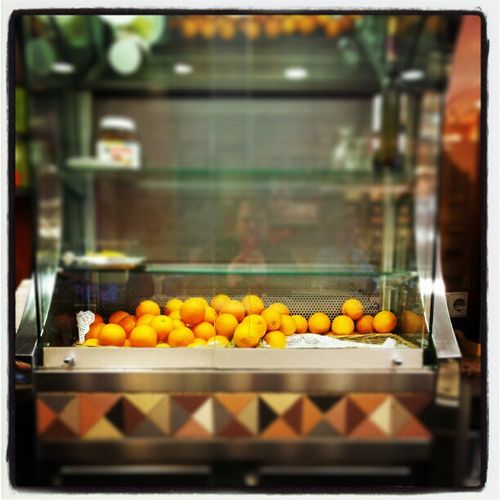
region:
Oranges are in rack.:
[86, 292, 377, 358]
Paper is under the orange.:
[284, 323, 404, 353]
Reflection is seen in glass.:
[78, 120, 361, 290]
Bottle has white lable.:
[62, 108, 173, 192]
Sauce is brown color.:
[91, 115, 141, 179]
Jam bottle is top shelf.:
[83, 109, 147, 180]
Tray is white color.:
[61, 241, 148, 281]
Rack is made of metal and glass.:
[18, 113, 470, 385]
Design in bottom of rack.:
[28, 393, 443, 458]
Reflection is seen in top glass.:
[100, 15, 378, 90]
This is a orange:
[330, 308, 356, 339]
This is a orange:
[342, 294, 364, 319]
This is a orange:
[373, 305, 399, 337]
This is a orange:
[354, 313, 376, 333]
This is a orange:
[398, 305, 425, 337]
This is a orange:
[303, 303, 338, 336]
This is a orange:
[291, 309, 307, 334]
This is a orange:
[277, 311, 297, 334]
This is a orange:
[263, 328, 285, 349]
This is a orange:
[231, 323, 259, 351]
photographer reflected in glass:
[191, 189, 302, 294]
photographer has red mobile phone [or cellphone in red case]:
[237, 227, 263, 264]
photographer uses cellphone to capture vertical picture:
[233, 222, 268, 262]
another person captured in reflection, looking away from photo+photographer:
[296, 202, 379, 297]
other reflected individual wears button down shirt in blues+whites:
[298, 242, 385, 294]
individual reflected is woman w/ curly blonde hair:
[318, 200, 362, 265]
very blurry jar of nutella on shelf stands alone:
[90, 112, 147, 167]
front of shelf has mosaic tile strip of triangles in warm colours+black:
[32, 387, 433, 443]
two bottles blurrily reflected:
[315, 119, 372, 200]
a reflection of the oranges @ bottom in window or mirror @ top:
[157, 12, 362, 55]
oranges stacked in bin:
[94, 288, 289, 364]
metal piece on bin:
[51, 356, 76, 368]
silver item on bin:
[363, 352, 431, 396]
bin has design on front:
[225, 395, 325, 439]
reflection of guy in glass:
[218, 193, 280, 284]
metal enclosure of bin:
[425, 300, 458, 359]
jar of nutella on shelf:
[80, 105, 146, 177]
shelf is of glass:
[154, 148, 355, 225]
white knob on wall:
[450, 285, 493, 373]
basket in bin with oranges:
[319, 328, 429, 370]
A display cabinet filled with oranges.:
[16, 65, 458, 472]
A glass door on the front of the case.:
[28, 49, 437, 371]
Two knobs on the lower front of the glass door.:
[44, 349, 423, 371]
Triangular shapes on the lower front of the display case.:
[31, 389, 429, 439]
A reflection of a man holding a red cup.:
[197, 188, 292, 301]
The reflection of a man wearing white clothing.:
[330, 121, 370, 168]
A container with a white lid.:
[95, 112, 141, 167]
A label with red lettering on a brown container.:
[90, 135, 140, 171]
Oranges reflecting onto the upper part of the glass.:
[170, 10, 361, 40]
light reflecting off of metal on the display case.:
[421, 274, 443, 301]